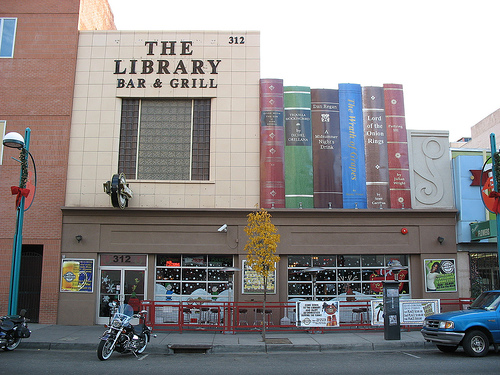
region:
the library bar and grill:
[76, 33, 257, 227]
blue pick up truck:
[411, 285, 496, 349]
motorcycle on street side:
[104, 299, 161, 358]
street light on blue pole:
[3, 120, 34, 343]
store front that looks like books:
[286, 70, 427, 201]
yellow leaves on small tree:
[242, 205, 286, 277]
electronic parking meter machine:
[356, 280, 411, 338]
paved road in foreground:
[8, 335, 498, 373]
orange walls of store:
[1, 10, 76, 285]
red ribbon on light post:
[2, 181, 57, 223]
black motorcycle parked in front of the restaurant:
[70, 294, 167, 364]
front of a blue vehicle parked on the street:
[425, 282, 497, 364]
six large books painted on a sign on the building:
[257, 75, 413, 221]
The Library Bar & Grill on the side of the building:
[108, 33, 225, 103]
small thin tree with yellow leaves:
[239, 208, 288, 340]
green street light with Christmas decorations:
[5, 122, 37, 333]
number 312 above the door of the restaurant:
[106, 250, 137, 265]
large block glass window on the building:
[113, 94, 218, 187]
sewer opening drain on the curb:
[164, 342, 212, 356]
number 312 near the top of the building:
[224, 32, 246, 50]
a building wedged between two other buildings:
[0, 1, 499, 336]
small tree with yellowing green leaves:
[243, 205, 283, 350]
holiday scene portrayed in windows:
[154, 253, 409, 321]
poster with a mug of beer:
[59, 257, 93, 289]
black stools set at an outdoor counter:
[131, 298, 470, 332]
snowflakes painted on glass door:
[96, 268, 121, 323]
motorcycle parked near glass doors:
[96, 252, 158, 362]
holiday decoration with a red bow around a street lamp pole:
[3, 125, 30, 317]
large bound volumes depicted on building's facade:
[258, 77, 411, 210]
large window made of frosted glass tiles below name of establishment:
[109, 37, 221, 183]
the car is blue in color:
[416, 297, 491, 357]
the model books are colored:
[257, 67, 412, 207]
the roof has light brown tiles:
[226, 97, 261, 203]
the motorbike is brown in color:
[87, 310, 152, 372]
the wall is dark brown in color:
[97, 217, 213, 249]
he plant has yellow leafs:
[234, 210, 276, 305]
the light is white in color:
[218, 222, 227, 233]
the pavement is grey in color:
[312, 352, 388, 373]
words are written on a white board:
[300, 296, 336, 328]